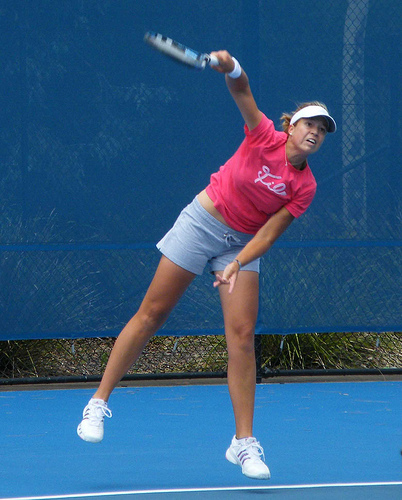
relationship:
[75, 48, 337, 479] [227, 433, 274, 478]
tennis player wearing shoe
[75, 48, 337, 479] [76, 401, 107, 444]
tennis player wearing shoe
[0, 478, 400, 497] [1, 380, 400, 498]
white line on blue court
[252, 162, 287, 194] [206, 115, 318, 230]
letters are on shirt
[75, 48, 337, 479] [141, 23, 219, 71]
tennis player swinging racket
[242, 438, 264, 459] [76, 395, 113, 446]
laces on shoe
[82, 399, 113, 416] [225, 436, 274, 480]
laces on shoe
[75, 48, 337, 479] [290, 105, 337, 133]
tennis player wearing visor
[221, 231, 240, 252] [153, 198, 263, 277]
string on shorts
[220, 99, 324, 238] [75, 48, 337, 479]
shirt on tennis player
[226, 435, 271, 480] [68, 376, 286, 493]
shoe on shoes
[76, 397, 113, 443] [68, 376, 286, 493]
shoe on shoes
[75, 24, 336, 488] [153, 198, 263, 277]
tennis player wearing shorts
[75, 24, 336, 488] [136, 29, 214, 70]
tennis player holds racket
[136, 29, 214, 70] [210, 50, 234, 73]
racket in hand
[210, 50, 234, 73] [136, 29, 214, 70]
hand has a racket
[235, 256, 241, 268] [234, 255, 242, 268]
bracelet on wrist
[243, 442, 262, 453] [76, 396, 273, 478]
pins on shoes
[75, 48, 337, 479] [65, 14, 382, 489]
tennis player playing tennis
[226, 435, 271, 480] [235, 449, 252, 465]
shoe has stripes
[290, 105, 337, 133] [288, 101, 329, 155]
visor on head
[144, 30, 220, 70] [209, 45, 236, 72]
racket in hand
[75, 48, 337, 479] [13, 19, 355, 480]
tennis player playing tennis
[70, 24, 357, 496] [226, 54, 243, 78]
girl has sweatband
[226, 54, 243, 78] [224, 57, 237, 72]
sweatband on wrist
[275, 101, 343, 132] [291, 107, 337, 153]
visor on head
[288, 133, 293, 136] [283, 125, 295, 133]
earring on ear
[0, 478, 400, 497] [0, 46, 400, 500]
white line on court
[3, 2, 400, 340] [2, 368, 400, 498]
divider behind court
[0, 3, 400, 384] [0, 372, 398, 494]
fence behind tennis court